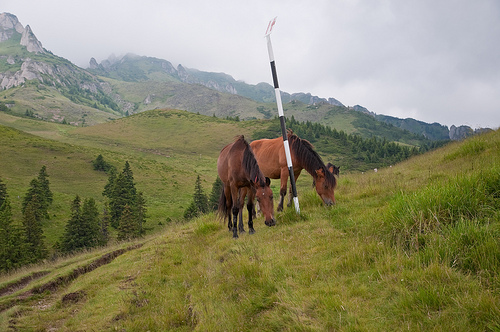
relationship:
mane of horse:
[243, 156, 258, 176] [213, 138, 280, 220]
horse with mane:
[247, 134, 338, 210] [288, 132, 337, 182]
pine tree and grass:
[51, 194, 109, 251] [0, 100, 497, 329]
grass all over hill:
[0, 100, 497, 329] [0, 131, 500, 330]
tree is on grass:
[119, 195, 141, 240] [42, 253, 232, 318]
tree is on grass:
[187, 172, 208, 212] [42, 253, 232, 318]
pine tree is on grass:
[51, 194, 109, 251] [42, 253, 232, 318]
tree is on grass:
[20, 192, 50, 262] [42, 253, 232, 318]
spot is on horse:
[258, 182, 274, 204] [206, 125, 290, 236]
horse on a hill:
[247, 127, 342, 213] [0, 131, 500, 330]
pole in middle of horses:
[265, 16, 307, 211] [220, 135, 340, 236]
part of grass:
[371, 231, 419, 253] [303, 226, 397, 296]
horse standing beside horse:
[213, 138, 280, 220] [247, 127, 342, 213]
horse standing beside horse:
[247, 127, 342, 213] [213, 138, 280, 220]